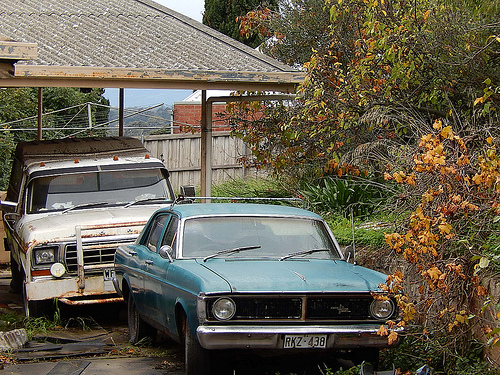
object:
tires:
[23, 277, 50, 321]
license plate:
[280, 333, 327, 349]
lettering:
[284, 335, 301, 347]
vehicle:
[1, 137, 181, 326]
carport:
[3, 1, 315, 202]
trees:
[406, 116, 500, 375]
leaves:
[380, 167, 417, 186]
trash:
[0, 324, 33, 352]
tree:
[2, 87, 111, 189]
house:
[170, 36, 310, 134]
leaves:
[373, 316, 409, 346]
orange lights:
[111, 154, 119, 161]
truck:
[3, 136, 194, 323]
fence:
[141, 132, 307, 199]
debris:
[0, 328, 115, 356]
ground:
[0, 268, 496, 370]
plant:
[318, 175, 369, 216]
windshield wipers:
[203, 244, 263, 262]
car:
[109, 202, 400, 374]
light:
[211, 298, 237, 320]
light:
[371, 298, 394, 321]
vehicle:
[103, 201, 403, 372]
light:
[33, 246, 56, 266]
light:
[28, 268, 56, 277]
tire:
[125, 289, 157, 345]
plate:
[281, 333, 329, 351]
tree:
[335, 4, 500, 163]